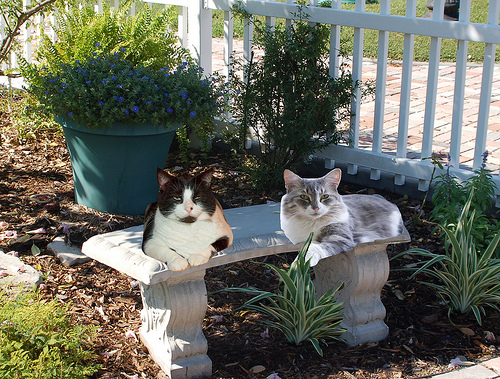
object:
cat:
[278, 169, 402, 267]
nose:
[185, 207, 192, 213]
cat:
[142, 167, 234, 272]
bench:
[81, 194, 413, 377]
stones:
[1, 237, 91, 286]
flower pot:
[55, 117, 184, 215]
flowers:
[48, 41, 202, 122]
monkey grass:
[388, 184, 499, 327]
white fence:
[0, 1, 499, 204]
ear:
[282, 167, 302, 189]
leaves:
[0, 286, 103, 378]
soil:
[0, 112, 499, 378]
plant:
[205, 233, 347, 356]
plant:
[211, 1, 378, 183]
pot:
[52, 114, 185, 215]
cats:
[277, 168, 405, 276]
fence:
[1, 0, 498, 201]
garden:
[1, 82, 498, 379]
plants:
[1, 1, 217, 213]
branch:
[0, 0, 56, 78]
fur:
[141, 167, 234, 273]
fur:
[280, 167, 404, 268]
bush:
[1, 287, 105, 377]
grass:
[81, 1, 499, 63]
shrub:
[433, 150, 496, 243]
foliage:
[207, 232, 349, 359]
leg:
[137, 269, 212, 377]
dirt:
[1, 85, 498, 379]